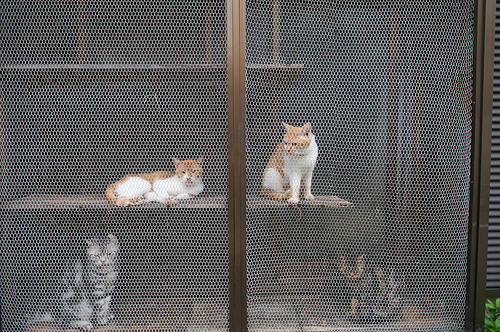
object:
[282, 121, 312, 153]
head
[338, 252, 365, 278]
head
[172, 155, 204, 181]
head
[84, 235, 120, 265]
head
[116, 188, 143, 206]
leg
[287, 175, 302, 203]
leg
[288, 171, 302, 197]
leg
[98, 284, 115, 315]
leg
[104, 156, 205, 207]
cat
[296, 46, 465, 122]
fence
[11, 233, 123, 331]
cat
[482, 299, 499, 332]
bush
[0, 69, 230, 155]
window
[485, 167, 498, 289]
corrugated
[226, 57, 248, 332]
frame bar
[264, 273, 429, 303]
wire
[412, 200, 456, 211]
wire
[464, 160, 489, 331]
frame bar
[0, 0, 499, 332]
photo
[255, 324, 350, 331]
ground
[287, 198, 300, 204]
front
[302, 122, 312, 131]
ear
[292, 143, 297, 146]
eyes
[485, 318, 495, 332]
leaves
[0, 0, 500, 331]
cage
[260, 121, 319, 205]
cat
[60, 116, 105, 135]
grate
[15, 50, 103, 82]
grate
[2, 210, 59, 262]
grate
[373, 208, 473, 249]
grate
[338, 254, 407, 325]
cat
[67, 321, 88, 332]
gray